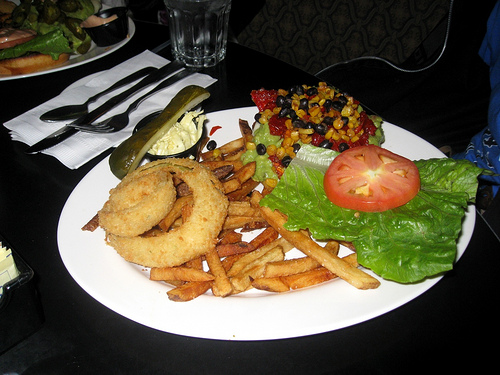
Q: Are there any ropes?
A: No, there are no ropes.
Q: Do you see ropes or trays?
A: No, there are no ropes or trays.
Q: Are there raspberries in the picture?
A: No, there are no raspberries.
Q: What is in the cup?
A: The coleslaw is in the cup.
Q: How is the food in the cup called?
A: The food is coleslaw.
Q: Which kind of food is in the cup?
A: The food is coleslaw.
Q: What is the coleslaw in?
A: The coleslaw is in the cup.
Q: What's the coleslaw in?
A: The coleslaw is in the cup.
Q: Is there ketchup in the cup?
A: No, there is coleslaw in the cup.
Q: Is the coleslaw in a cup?
A: Yes, the coleslaw is in a cup.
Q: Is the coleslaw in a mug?
A: No, the coleslaw is in a cup.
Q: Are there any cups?
A: Yes, there is a cup.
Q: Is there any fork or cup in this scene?
A: Yes, there is a cup.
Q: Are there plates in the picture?
A: Yes, there is a plate.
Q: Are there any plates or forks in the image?
A: Yes, there is a plate.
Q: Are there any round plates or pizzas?
A: Yes, there is a round plate.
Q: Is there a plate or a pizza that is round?
A: Yes, the plate is round.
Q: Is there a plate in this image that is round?
A: Yes, there is a round plate.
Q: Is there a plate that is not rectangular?
A: Yes, there is a round plate.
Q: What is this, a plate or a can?
A: This is a plate.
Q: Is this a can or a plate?
A: This is a plate.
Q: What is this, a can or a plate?
A: This is a plate.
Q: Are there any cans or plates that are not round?
A: No, there is a plate but it is round.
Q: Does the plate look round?
A: Yes, the plate is round.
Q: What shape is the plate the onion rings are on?
A: The plate is round.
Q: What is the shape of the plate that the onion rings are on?
A: The plate is round.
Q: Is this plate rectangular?
A: No, the plate is round.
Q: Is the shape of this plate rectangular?
A: No, the plate is round.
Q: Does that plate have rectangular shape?
A: No, the plate is round.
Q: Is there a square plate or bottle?
A: No, there is a plate but it is round.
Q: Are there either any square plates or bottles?
A: No, there is a plate but it is round.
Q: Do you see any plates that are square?
A: No, there is a plate but it is round.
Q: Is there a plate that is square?
A: No, there is a plate but it is round.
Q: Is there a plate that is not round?
A: No, there is a plate but it is round.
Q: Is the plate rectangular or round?
A: The plate is round.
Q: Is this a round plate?
A: Yes, this is a round plate.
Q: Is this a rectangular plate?
A: No, this is a round plate.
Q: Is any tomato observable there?
A: Yes, there is a tomato.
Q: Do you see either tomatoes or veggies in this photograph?
A: Yes, there is a tomato.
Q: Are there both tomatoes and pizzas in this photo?
A: No, there is a tomato but no pizzas.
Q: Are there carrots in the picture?
A: No, there are no carrots.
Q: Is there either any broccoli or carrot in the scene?
A: No, there are no carrots or broccoli.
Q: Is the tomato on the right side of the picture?
A: Yes, the tomato is on the right of the image.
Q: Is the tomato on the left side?
A: No, the tomato is on the right of the image.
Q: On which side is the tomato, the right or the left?
A: The tomato is on the right of the image.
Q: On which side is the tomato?
A: The tomato is on the right of the image.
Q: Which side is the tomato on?
A: The tomato is on the right of the image.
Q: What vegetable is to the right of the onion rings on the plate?
A: The vegetable is a tomato.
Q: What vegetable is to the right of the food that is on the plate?
A: The vegetable is a tomato.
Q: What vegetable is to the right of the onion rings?
A: The vegetable is a tomato.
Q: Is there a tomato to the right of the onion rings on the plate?
A: Yes, there is a tomato to the right of the onion rings.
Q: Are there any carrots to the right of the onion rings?
A: No, there is a tomato to the right of the onion rings.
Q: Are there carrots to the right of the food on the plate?
A: No, there is a tomato to the right of the onion rings.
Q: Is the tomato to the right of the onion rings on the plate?
A: Yes, the tomato is to the right of the onion rings.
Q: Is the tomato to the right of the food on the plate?
A: Yes, the tomato is to the right of the onion rings.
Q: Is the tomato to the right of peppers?
A: No, the tomato is to the right of the onion rings.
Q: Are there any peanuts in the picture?
A: No, there are no peanuts.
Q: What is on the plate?
A: The onion rings are on the plate.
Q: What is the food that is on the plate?
A: The food is onion rings.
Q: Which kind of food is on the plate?
A: The food is onion rings.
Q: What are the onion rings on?
A: The onion rings are on the plate.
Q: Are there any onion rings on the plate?
A: Yes, there are onion rings on the plate.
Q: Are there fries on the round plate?
A: No, there are onion rings on the plate.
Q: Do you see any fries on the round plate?
A: No, there are onion rings on the plate.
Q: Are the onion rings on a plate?
A: Yes, the onion rings are on a plate.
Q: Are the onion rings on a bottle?
A: No, the onion rings are on a plate.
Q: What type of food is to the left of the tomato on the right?
A: The food is onion rings.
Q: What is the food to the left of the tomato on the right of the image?
A: The food is onion rings.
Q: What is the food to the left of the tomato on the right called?
A: The food is onion rings.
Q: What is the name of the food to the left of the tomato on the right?
A: The food is onion rings.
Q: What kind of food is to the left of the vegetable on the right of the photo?
A: The food is onion rings.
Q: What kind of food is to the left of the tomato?
A: The food is onion rings.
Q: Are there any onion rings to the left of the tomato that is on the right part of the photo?
A: Yes, there are onion rings to the left of the tomato.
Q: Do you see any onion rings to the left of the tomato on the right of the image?
A: Yes, there are onion rings to the left of the tomato.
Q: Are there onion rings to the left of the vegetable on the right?
A: Yes, there are onion rings to the left of the tomato.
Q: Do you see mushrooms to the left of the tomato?
A: No, there are onion rings to the left of the tomato.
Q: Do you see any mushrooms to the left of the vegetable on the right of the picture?
A: No, there are onion rings to the left of the tomato.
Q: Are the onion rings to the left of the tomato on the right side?
A: Yes, the onion rings are to the left of the tomato.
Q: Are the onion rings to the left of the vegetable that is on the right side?
A: Yes, the onion rings are to the left of the tomato.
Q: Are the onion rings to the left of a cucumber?
A: No, the onion rings are to the left of the tomato.